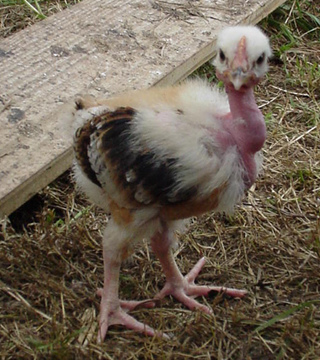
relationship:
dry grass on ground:
[288, 31, 308, 83] [278, 115, 302, 140]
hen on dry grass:
[46, 34, 286, 292] [288, 31, 308, 83]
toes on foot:
[193, 266, 224, 314] [167, 260, 239, 329]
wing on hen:
[87, 119, 185, 202] [46, 34, 286, 292]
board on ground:
[83, 32, 127, 46] [278, 115, 302, 140]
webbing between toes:
[104, 307, 123, 332] [193, 266, 224, 314]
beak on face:
[230, 54, 250, 106] [224, 20, 261, 87]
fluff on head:
[215, 26, 259, 36] [222, 28, 277, 92]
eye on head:
[214, 45, 226, 64] [222, 28, 277, 92]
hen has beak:
[46, 34, 286, 292] [230, 54, 250, 106]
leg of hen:
[99, 221, 129, 302] [46, 34, 286, 292]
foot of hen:
[167, 260, 239, 329] [46, 34, 286, 292]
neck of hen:
[226, 87, 261, 131] [46, 34, 286, 292]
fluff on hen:
[215, 26, 259, 36] [46, 34, 286, 292]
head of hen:
[222, 28, 277, 92] [46, 34, 286, 292]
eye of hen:
[210, 42, 235, 71] [46, 34, 286, 292]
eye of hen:
[254, 38, 271, 69] [46, 34, 286, 292]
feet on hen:
[94, 273, 229, 340] [46, 34, 286, 292]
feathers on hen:
[187, 88, 223, 118] [46, 34, 286, 292]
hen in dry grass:
[46, 34, 286, 292] [288, 31, 308, 83]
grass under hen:
[281, 19, 299, 53] [46, 34, 286, 292]